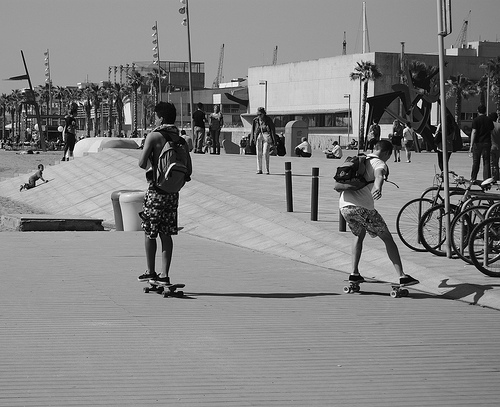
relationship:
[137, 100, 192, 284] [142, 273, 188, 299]
man riding skateboard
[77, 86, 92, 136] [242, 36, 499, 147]
palm tree next to building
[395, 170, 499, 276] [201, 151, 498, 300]
bicycles on sidewalk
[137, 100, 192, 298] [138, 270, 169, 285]
man wears shoes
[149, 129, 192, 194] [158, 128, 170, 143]
backpack has black strap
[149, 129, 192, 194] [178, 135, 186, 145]
backpack has black strap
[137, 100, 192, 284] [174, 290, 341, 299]
man has shadow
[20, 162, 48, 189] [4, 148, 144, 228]
child on slope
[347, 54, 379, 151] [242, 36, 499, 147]
palm tree aside building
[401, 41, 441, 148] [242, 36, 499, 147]
palm tree aside building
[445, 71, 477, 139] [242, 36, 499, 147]
palm tree aside building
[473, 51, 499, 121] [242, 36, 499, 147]
palm tree aside building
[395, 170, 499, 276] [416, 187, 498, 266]
bicycles parked on rack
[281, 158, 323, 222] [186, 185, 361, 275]
black poles next to slope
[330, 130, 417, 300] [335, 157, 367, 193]
boy has backpack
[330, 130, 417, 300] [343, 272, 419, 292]
boy rides skateboard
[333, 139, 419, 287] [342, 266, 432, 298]
boy riding skateboard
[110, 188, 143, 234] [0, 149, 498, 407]
trashcan next to sidewalk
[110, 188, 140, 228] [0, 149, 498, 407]
trashcan next to sidewalk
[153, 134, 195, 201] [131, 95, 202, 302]
backpack on back of skateboarder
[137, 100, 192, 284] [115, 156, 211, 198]
man wearing back pack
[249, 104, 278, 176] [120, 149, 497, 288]
woman looking at sidewalk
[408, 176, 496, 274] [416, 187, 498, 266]
bicycles parked on rack